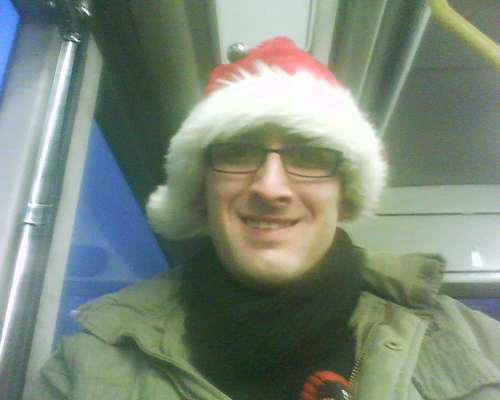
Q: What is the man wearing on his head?
A: A santa hat.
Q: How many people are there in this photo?
A: One.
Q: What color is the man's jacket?
A: Green.